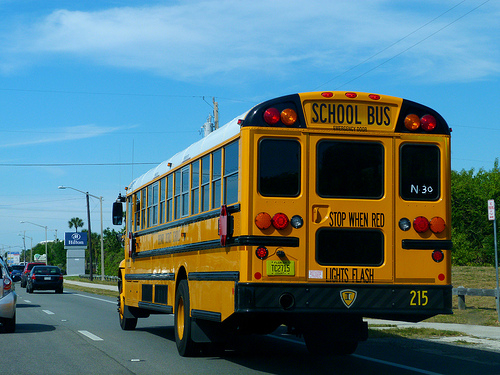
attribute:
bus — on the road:
[60, 99, 468, 360]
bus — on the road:
[162, 126, 486, 374]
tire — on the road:
[171, 278, 224, 355]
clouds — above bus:
[9, 40, 141, 135]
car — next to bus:
[25, 263, 66, 293]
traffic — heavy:
[13, 253, 83, 311]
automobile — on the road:
[110, 89, 452, 356]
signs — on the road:
[116, 203, 232, 273]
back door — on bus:
[307, 132, 397, 285]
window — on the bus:
[245, 132, 309, 206]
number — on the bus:
[406, 288, 430, 310]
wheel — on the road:
[134, 264, 229, 346]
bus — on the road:
[105, 87, 456, 368]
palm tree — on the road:
[67, 212, 88, 231]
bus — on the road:
[397, 249, 457, 304]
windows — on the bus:
[255, 139, 311, 195]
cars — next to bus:
[0, 250, 85, 332]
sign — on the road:
[479, 196, 497, 226]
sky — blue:
[2, 31, 239, 148]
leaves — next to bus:
[443, 157, 498, 269]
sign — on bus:
[60, 230, 96, 287]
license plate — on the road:
[268, 258, 298, 275]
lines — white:
[32, 289, 139, 374]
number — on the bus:
[401, 285, 441, 312]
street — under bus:
[20, 286, 212, 373]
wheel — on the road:
[164, 275, 202, 367]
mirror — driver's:
[104, 197, 126, 229]